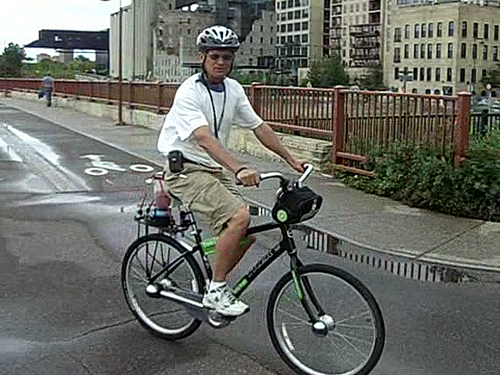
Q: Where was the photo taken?
A: It was taken at the street.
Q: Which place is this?
A: It is a street.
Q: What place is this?
A: It is a street.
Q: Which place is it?
A: It is a street.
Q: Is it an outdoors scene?
A: Yes, it is outdoors.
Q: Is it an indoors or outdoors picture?
A: It is outdoors.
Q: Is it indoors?
A: No, it is outdoors.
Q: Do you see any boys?
A: No, there are no boys.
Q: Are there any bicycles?
A: Yes, there is a bicycle.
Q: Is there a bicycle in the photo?
A: Yes, there is a bicycle.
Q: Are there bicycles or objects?
A: Yes, there is a bicycle.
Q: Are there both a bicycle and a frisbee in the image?
A: No, there is a bicycle but no frisbees.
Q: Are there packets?
A: No, there are no packets.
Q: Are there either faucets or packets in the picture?
A: No, there are no packets or faucets.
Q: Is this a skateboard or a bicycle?
A: This is a bicycle.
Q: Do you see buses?
A: No, there are no buses.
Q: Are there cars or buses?
A: No, there are no buses or cars.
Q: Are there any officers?
A: No, there are no officers.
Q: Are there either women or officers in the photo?
A: No, there are no officers or women.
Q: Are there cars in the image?
A: No, there are no cars.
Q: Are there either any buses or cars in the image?
A: No, there are no cars or buses.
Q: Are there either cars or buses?
A: No, there are no cars or buses.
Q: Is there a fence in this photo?
A: Yes, there is a fence.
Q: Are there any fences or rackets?
A: Yes, there is a fence.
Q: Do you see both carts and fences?
A: No, there is a fence but no carts.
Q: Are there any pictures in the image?
A: No, there are no pictures.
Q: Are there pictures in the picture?
A: No, there are no pictures.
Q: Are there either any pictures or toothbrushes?
A: No, there are no pictures or toothbrushes.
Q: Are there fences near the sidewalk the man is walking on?
A: Yes, there is a fence near the sidewalk.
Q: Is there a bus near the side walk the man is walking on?
A: No, there is a fence near the sidewalk.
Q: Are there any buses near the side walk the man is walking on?
A: No, there is a fence near the sidewalk.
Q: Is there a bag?
A: Yes, there is a bag.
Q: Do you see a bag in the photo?
A: Yes, there is a bag.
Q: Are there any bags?
A: Yes, there is a bag.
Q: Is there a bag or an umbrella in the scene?
A: Yes, there is a bag.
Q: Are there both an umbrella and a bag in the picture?
A: No, there is a bag but no umbrellas.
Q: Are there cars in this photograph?
A: No, there are no cars.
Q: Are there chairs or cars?
A: No, there are no cars or chairs.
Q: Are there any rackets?
A: No, there are no rackets.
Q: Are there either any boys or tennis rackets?
A: No, there are no tennis rackets or boys.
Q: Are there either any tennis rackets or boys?
A: No, there are no tennis rackets or boys.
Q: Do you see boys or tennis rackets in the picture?
A: No, there are no tennis rackets or boys.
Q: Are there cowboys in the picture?
A: No, there are no cowboys.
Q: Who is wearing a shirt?
A: The man is wearing a shirt.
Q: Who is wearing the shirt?
A: The man is wearing a shirt.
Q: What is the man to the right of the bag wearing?
A: The man is wearing a shirt.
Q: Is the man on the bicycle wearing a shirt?
A: Yes, the man is wearing a shirt.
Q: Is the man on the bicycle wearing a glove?
A: No, the man is wearing a shirt.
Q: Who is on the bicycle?
A: The man is on the bicycle.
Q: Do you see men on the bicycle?
A: Yes, there is a man on the bicycle.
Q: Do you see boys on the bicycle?
A: No, there is a man on the bicycle.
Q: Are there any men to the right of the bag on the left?
A: Yes, there is a man to the right of the bag.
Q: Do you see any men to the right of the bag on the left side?
A: Yes, there is a man to the right of the bag.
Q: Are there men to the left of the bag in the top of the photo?
A: No, the man is to the right of the bag.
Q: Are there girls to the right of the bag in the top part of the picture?
A: No, there is a man to the right of the bag.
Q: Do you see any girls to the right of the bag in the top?
A: No, there is a man to the right of the bag.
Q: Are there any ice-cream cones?
A: No, there are no ice-cream cones.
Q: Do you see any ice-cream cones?
A: No, there are no ice-cream cones.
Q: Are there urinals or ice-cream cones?
A: No, there are no ice-cream cones or urinals.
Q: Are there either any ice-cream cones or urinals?
A: No, there are no ice-cream cones or urinals.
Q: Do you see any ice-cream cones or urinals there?
A: No, there are no ice-cream cones or urinals.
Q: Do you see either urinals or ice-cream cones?
A: No, there are no ice-cream cones or urinals.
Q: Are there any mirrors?
A: No, there are no mirrors.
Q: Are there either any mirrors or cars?
A: No, there are no mirrors or cars.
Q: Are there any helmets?
A: Yes, there is a helmet.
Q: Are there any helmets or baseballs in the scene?
A: Yes, there is a helmet.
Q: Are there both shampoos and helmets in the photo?
A: No, there is a helmet but no shampoos.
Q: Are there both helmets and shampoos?
A: No, there is a helmet but no shampoos.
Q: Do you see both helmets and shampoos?
A: No, there is a helmet but no shampoos.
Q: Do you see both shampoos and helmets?
A: No, there is a helmet but no shampoos.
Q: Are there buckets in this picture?
A: No, there are no buckets.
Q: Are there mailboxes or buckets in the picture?
A: No, there are no buckets or mailboxes.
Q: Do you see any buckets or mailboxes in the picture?
A: No, there are no buckets or mailboxes.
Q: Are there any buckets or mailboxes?
A: No, there are no buckets or mailboxes.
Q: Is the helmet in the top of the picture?
A: Yes, the helmet is in the top of the image.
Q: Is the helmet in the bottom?
A: No, the helmet is in the top of the image.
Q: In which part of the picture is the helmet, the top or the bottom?
A: The helmet is in the top of the image.